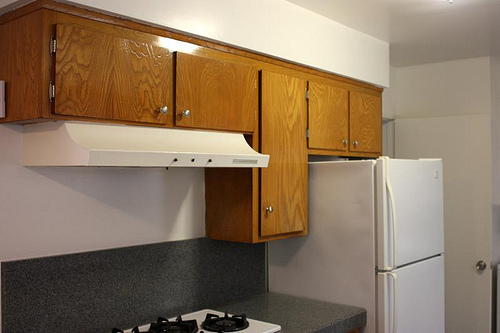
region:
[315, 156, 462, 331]
plain white refrigerator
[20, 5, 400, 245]
kitchen cabinets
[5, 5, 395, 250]
wooden kitchen cabinets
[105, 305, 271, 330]
gas stovetop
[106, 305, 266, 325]
stove top burners turned off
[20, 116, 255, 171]
kitchen air vent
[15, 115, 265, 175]
air vent above the stove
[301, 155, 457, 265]
freezer portion of the fridge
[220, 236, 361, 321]
dark grey counter top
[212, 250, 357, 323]
empty space on a counter top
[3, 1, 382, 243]
The kitchen cabinets are wooden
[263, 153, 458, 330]
The refrigerator is white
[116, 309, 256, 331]
The eyes on the stove are black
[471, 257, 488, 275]
The door knob is silver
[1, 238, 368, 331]
The counter top is gray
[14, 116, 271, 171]
The hood to the stove is white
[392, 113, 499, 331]
The door is white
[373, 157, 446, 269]
The freezer door has a handle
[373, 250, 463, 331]
The refrigerator door has a white handle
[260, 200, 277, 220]
The cabinet knobs are silver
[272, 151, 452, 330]
white fridge with white handles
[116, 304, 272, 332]
black burners on stove top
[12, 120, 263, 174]
hood over oven range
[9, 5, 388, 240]
cabiners over gray countertop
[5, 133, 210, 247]
white wall behind stovetop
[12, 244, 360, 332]
gray countertops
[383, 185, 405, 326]
white handles on white fridge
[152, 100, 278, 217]
three knobs on cabinets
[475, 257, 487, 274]
silver door knob on white door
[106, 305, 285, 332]
white stovetop with black burners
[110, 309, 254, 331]
Ranges on the stove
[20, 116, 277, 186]
Fan and light top to stove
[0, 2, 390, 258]
Brown wooden kitchen cabinets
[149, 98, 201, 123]
Handles on kitchen cabinets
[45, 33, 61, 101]
Hinges on kitchen cabinets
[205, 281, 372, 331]
Gray kitchen counter top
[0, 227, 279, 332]
Gray kitchen counter trim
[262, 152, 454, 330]
White fridge and freezer combo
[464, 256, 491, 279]
Silver door handle on white door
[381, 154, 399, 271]
Handle to freezer door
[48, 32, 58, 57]
A metallic cupboard hinge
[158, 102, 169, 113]
A metallic cupboard knob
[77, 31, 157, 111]
Brown veneer of cupboard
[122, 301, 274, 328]
A stove on the surface of table top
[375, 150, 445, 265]
The door of the freezer compartment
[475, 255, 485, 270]
The kitchen door knob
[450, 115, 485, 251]
The white kitchen door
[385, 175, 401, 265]
The handle of the freezer compartment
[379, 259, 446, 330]
The fridge compartment door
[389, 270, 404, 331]
The handle of the fridge compartment door